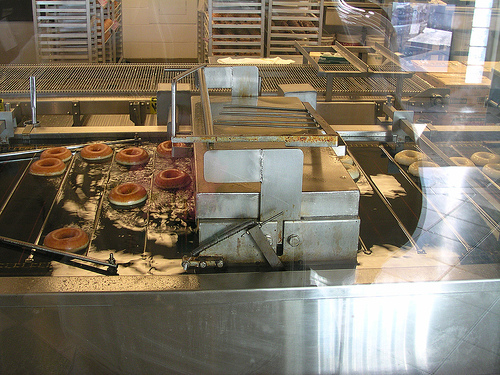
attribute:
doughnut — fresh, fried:
[45, 225, 91, 251]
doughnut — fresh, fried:
[109, 178, 149, 206]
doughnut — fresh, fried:
[155, 165, 193, 192]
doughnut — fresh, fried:
[31, 159, 67, 176]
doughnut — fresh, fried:
[82, 140, 114, 161]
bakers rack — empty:
[32, 0, 124, 64]